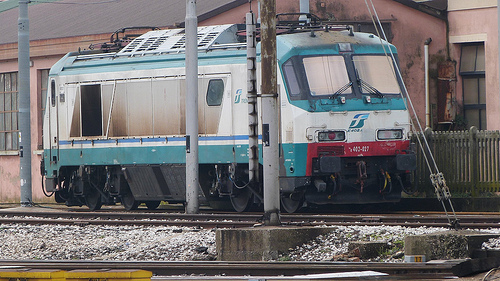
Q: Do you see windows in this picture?
A: Yes, there is a window.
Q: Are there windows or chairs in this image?
A: Yes, there is a window.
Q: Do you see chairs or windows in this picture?
A: Yes, there is a window.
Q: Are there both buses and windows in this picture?
A: No, there is a window but no buses.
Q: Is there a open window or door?
A: Yes, there is an open window.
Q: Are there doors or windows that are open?
A: Yes, the window is open.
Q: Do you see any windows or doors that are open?
A: Yes, the window is open.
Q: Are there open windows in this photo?
A: Yes, there is an open window.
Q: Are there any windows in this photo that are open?
A: Yes, there is a window that is open.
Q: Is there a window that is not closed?
A: Yes, there is a open window.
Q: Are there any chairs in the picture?
A: No, there are no chairs.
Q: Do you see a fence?
A: Yes, there is a fence.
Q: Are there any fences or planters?
A: Yes, there is a fence.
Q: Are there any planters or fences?
A: Yes, there is a fence.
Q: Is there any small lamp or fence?
A: Yes, there is a small fence.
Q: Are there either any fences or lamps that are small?
A: Yes, the fence is small.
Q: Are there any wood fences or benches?
A: Yes, there is a wood fence.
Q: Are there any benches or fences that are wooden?
A: Yes, the fence is wooden.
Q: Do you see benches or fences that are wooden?
A: Yes, the fence is wooden.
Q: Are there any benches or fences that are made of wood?
A: Yes, the fence is made of wood.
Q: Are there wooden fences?
A: Yes, there is a wood fence.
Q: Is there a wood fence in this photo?
A: Yes, there is a wood fence.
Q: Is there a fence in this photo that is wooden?
A: Yes, there is a fence that is wooden.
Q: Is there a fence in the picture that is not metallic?
A: Yes, there is a wooden fence.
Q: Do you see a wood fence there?
A: Yes, there is a fence that is made of wood.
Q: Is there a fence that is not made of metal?
A: Yes, there is a fence that is made of wood.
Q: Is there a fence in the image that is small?
A: Yes, there is a small fence.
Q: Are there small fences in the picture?
A: Yes, there is a small fence.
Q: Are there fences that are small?
A: Yes, there is a fence that is small.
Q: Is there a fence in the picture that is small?
A: Yes, there is a fence that is small.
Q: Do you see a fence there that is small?
A: Yes, there is a fence that is small.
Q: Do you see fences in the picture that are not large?
A: Yes, there is a small fence.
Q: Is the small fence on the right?
A: Yes, the fence is on the right of the image.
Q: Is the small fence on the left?
A: No, the fence is on the right of the image.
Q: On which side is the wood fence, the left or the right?
A: The fence is on the right of the image.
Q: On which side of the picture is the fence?
A: The fence is on the right of the image.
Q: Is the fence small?
A: Yes, the fence is small.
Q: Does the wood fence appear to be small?
A: Yes, the fence is small.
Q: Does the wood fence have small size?
A: Yes, the fence is small.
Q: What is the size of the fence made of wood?
A: The fence is small.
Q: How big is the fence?
A: The fence is small.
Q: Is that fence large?
A: No, the fence is small.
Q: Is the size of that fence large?
A: No, the fence is small.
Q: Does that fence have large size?
A: No, the fence is small.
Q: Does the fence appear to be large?
A: No, the fence is small.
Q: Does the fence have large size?
A: No, the fence is small.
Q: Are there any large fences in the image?
A: No, there is a fence but it is small.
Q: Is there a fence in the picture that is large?
A: No, there is a fence but it is small.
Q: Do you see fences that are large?
A: No, there is a fence but it is small.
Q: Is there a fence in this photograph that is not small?
A: No, there is a fence but it is small.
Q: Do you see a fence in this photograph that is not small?
A: No, there is a fence but it is small.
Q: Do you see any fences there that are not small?
A: No, there is a fence but it is small.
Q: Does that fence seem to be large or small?
A: The fence is small.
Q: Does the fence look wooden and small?
A: Yes, the fence is wooden and small.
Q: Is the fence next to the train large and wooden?
A: No, the fence is wooden but small.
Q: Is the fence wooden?
A: Yes, the fence is wooden.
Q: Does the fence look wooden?
A: Yes, the fence is wooden.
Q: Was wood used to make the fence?
A: Yes, the fence is made of wood.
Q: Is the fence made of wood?
A: Yes, the fence is made of wood.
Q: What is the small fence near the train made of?
A: The fence is made of wood.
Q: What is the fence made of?
A: The fence is made of wood.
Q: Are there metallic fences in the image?
A: No, there is a fence but it is wooden.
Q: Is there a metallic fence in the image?
A: No, there is a fence but it is wooden.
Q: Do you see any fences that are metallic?
A: No, there is a fence but it is wooden.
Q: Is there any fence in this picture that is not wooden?
A: No, there is a fence but it is wooden.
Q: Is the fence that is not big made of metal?
A: No, the fence is made of wood.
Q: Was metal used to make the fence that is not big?
A: No, the fence is made of wood.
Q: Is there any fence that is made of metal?
A: No, there is a fence but it is made of wood.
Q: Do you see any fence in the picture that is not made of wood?
A: No, there is a fence but it is made of wood.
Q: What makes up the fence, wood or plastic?
A: The fence is made of wood.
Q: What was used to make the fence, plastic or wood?
A: The fence is made of wood.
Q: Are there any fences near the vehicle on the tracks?
A: Yes, there is a fence near the train.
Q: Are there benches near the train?
A: No, there is a fence near the train.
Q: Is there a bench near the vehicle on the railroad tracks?
A: No, there is a fence near the train.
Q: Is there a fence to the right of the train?
A: Yes, there is a fence to the right of the train.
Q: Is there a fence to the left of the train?
A: No, the fence is to the right of the train.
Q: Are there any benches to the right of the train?
A: No, there is a fence to the right of the train.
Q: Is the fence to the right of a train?
A: Yes, the fence is to the right of a train.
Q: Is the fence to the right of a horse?
A: No, the fence is to the right of a train.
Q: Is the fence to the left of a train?
A: No, the fence is to the right of a train.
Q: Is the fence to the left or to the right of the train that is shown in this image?
A: The fence is to the right of the train.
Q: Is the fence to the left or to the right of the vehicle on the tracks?
A: The fence is to the right of the train.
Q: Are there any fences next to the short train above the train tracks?
A: Yes, there is a fence next to the train.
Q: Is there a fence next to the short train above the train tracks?
A: Yes, there is a fence next to the train.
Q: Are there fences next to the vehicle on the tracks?
A: Yes, there is a fence next to the train.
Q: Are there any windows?
A: Yes, there is a window.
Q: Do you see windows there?
A: Yes, there is a window.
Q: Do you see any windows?
A: Yes, there is a window.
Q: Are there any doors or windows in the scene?
A: Yes, there is a window.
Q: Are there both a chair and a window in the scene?
A: No, there is a window but no chairs.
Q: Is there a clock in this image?
A: No, there are no clocks.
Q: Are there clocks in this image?
A: No, there are no clocks.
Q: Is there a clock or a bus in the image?
A: No, there are no clocks or buses.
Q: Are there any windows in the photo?
A: Yes, there is a window.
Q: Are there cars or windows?
A: Yes, there is a window.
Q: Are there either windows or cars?
A: Yes, there is a window.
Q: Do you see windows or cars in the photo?
A: Yes, there is a window.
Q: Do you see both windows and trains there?
A: Yes, there are both a window and a train.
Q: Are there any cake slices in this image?
A: No, there are no cake slices.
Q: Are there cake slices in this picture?
A: No, there are no cake slices.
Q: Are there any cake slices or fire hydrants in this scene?
A: No, there are no cake slices or fire hydrants.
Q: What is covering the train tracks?
A: The gravel is covering the train tracks.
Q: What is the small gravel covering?
A: The gravel is covering the tracks.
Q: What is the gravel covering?
A: The gravel is covering the tracks.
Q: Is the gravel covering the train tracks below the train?
A: Yes, the gravel is covering the tracks.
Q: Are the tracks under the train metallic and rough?
A: Yes, the train tracks are metallic and rough.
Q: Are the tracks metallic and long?
A: Yes, the tracks are metallic and long.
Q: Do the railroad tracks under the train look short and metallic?
A: No, the train tracks are metallic but long.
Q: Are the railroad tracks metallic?
A: Yes, the railroad tracks are metallic.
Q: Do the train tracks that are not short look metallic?
A: Yes, the train tracks are metallic.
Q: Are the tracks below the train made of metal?
A: Yes, the tracks are made of metal.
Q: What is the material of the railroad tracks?
A: The railroad tracks are made of metal.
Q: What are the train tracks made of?
A: The railroad tracks are made of metal.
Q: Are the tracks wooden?
A: No, the tracks are metallic.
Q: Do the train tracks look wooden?
A: No, the train tracks are metallic.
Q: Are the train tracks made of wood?
A: No, the train tracks are made of metal.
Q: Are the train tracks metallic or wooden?
A: The train tracks are metallic.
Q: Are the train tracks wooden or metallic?
A: The train tracks are metallic.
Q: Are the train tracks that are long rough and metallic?
A: Yes, the tracks are rough and metallic.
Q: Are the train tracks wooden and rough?
A: No, the train tracks are rough but metallic.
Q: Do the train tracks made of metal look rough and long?
A: Yes, the train tracks are rough and long.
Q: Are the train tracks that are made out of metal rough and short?
A: No, the tracks are rough but long.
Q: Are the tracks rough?
A: Yes, the tracks are rough.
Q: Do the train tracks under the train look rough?
A: Yes, the train tracks are rough.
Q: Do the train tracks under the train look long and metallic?
A: Yes, the tracks are long and metallic.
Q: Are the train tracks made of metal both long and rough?
A: Yes, the tracks are long and rough.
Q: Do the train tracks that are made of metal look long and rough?
A: Yes, the tracks are long and rough.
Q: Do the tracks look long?
A: Yes, the tracks are long.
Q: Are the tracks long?
A: Yes, the tracks are long.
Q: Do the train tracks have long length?
A: Yes, the train tracks are long.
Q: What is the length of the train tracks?
A: The train tracks are long.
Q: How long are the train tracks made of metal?
A: The train tracks are long.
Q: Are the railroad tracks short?
A: No, the railroad tracks are long.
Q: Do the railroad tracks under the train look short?
A: No, the railroad tracks are long.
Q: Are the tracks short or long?
A: The tracks are long.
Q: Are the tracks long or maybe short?
A: The tracks are long.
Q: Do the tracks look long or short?
A: The tracks are long.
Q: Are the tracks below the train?
A: Yes, the tracks are below the train.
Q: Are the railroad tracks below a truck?
A: No, the railroad tracks are below the train.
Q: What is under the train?
A: The train tracks are under the train.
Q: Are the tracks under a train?
A: Yes, the tracks are under a train.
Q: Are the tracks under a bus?
A: No, the tracks are under a train.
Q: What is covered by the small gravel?
A: The tracks are covered by the gravel.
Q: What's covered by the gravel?
A: The tracks are covered by the gravel.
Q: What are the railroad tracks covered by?
A: The railroad tracks are covered by the gravel.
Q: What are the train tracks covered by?
A: The railroad tracks are covered by the gravel.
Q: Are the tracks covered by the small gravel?
A: Yes, the tracks are covered by the gravel.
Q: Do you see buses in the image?
A: No, there are no buses.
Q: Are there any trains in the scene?
A: Yes, there is a train.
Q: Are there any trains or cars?
A: Yes, there is a train.